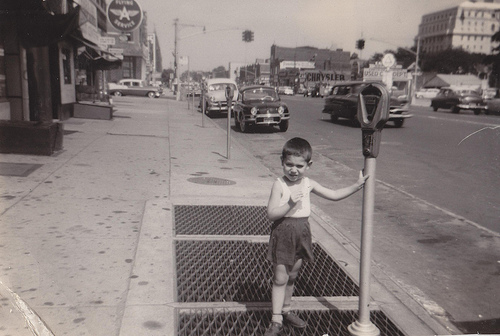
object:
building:
[98, 8, 154, 93]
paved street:
[183, 83, 500, 335]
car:
[198, 77, 240, 117]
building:
[411, 2, 500, 73]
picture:
[0, 0, 500, 334]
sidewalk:
[0, 94, 456, 336]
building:
[0, 0, 145, 157]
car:
[229, 83, 292, 134]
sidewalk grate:
[173, 201, 410, 336]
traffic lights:
[357, 36, 422, 109]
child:
[265, 136, 372, 335]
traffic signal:
[242, 29, 254, 41]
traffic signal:
[353, 38, 365, 50]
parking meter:
[349, 79, 395, 333]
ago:
[0, 0, 500, 334]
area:
[54, 108, 306, 191]